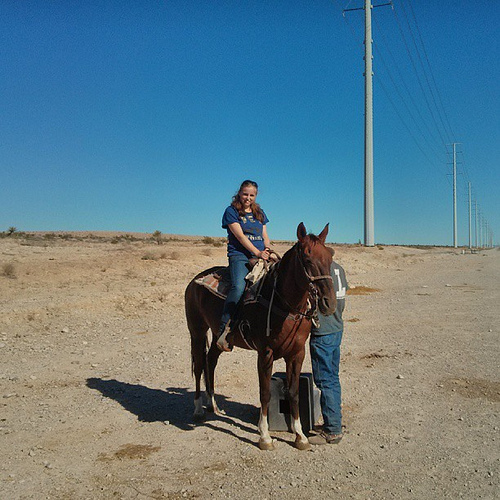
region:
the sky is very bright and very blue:
[1, 1, 499, 259]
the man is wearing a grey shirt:
[310, 256, 356, 334]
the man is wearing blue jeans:
[300, 325, 350, 450]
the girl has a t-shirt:
[216, 198, 277, 264]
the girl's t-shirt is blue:
[220, 200, 272, 260]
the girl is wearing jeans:
[202, 250, 264, 341]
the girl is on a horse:
[218, 175, 279, 362]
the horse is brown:
[178, 220, 338, 454]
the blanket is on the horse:
[187, 257, 270, 311]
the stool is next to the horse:
[263, 364, 319, 448]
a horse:
[133, 178, 321, 457]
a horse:
[137, 30, 317, 370]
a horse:
[185, 150, 432, 425]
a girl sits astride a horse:
[179, 165, 349, 470]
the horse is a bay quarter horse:
[171, 161, 368, 443]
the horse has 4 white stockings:
[185, 379, 317, 484]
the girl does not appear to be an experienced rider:
[211, 148, 301, 374]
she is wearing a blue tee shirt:
[196, 155, 278, 296]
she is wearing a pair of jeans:
[206, 237, 251, 350]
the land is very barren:
[26, 248, 171, 420]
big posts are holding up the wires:
[361, 5, 495, 272]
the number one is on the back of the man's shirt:
[333, 260, 351, 317]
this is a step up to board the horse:
[261, 356, 328, 449]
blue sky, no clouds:
[4, 2, 346, 157]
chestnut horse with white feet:
[164, 217, 333, 454]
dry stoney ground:
[2, 399, 491, 499]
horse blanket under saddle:
[187, 266, 262, 303]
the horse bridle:
[296, 240, 339, 326]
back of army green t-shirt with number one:
[307, 257, 351, 334]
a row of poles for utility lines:
[328, 3, 498, 257]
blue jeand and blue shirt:
[221, 203, 273, 337]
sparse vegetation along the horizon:
[0, 223, 491, 252]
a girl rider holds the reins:
[231, 178, 295, 373]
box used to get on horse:
[250, 365, 332, 430]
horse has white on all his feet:
[184, 403, 328, 456]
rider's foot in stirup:
[200, 282, 278, 392]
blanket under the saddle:
[183, 252, 294, 314]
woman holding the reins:
[242, 239, 292, 272]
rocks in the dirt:
[247, 463, 498, 490]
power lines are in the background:
[328, 6, 496, 230]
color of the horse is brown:
[182, 257, 381, 371]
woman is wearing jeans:
[218, 237, 248, 323]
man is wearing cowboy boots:
[312, 410, 348, 449]